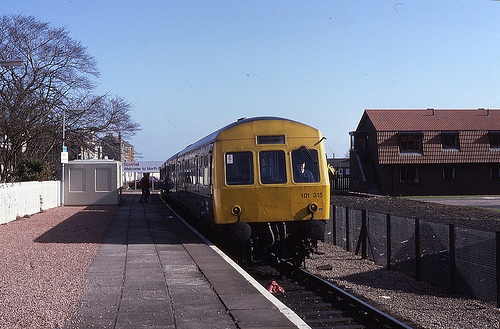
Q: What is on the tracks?
A: Train.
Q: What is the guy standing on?
A: Cement.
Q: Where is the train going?
A: Down the track.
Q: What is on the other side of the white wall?
A: Trees.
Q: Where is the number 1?
A: On the train.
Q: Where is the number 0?
A: On the train.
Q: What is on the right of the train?
A: A house.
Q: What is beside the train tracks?
A: A fence.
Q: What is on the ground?
A: Shadows.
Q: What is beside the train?
A: A sidewalk.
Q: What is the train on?
A: Tracks.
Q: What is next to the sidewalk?
A: Gravel.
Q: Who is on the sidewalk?
A: Passengers.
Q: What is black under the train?
A: Train tracks.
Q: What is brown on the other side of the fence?
A: A building.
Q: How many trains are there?
A: 1.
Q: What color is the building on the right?
A: Brown.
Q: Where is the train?
A: On the tracks.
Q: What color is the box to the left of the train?
A: White.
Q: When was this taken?
A: Daytime.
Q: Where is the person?
A: Standing by the train.